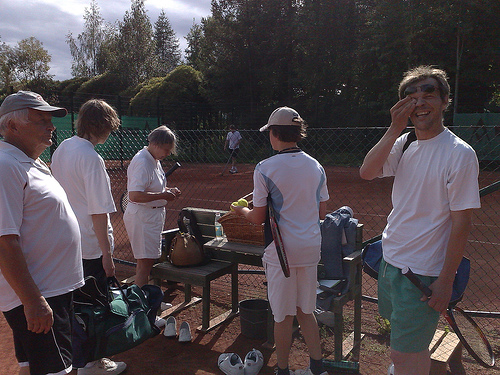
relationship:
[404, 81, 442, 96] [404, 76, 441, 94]
sunglasses on forehead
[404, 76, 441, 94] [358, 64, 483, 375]
forehead on man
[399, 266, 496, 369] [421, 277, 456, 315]
racket in hand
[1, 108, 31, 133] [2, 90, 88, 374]
hair of man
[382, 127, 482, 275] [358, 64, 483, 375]
shirt of man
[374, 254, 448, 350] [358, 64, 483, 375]
shorts of man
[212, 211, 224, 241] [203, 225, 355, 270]
bottle on table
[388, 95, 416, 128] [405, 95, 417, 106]
hand on eye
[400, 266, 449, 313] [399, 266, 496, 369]
handle of racket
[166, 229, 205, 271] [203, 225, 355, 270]
bag on table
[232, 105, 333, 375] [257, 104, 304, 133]
man wearing hat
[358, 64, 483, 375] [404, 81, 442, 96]
man wearing sunglasses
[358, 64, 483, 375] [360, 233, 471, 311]
man carrying bag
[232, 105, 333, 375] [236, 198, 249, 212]
man holding balls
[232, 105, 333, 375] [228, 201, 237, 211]
man holding balls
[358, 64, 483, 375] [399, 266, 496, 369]
man holding racket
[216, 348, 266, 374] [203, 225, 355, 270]
shoes under table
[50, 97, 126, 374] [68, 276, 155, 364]
man carrying bag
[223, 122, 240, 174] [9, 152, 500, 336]
man on court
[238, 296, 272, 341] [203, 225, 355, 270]
bucket under table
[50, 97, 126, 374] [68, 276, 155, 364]
man holding bag